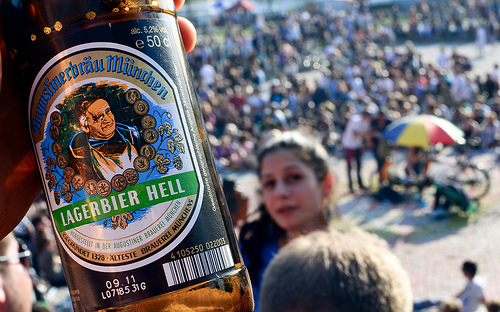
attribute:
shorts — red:
[340, 143, 368, 167]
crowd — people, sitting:
[198, 33, 498, 178]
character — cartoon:
[64, 90, 154, 195]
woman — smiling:
[244, 132, 350, 228]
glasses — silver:
[0, 238, 38, 270]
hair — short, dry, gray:
[252, 220, 420, 310]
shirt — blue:
[242, 227, 283, 289]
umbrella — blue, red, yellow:
[374, 105, 474, 155]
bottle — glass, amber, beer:
[9, 10, 278, 310]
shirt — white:
[337, 114, 377, 151]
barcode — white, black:
[154, 240, 261, 291]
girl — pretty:
[247, 129, 362, 243]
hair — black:
[236, 135, 341, 177]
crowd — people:
[178, 1, 496, 183]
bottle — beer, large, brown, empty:
[7, 6, 255, 310]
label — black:
[9, 9, 270, 308]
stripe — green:
[44, 168, 212, 237]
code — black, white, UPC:
[151, 239, 245, 290]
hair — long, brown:
[235, 206, 292, 264]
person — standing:
[334, 91, 392, 203]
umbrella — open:
[379, 110, 473, 155]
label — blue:
[14, 21, 238, 289]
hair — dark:
[259, 127, 332, 182]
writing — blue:
[32, 50, 166, 130]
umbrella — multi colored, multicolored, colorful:
[385, 115, 465, 145]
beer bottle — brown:
[10, 10, 248, 310]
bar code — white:
[162, 244, 232, 291]